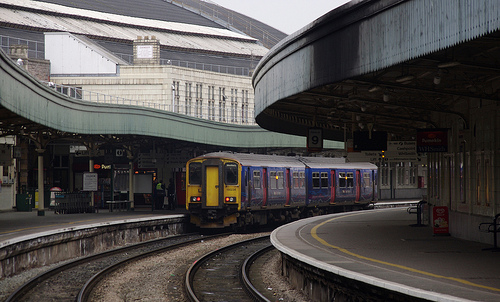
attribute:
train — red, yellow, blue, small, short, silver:
[181, 149, 381, 231]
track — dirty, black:
[6, 226, 236, 301]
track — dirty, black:
[185, 232, 281, 301]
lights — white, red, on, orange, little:
[222, 194, 238, 205]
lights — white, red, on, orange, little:
[187, 193, 204, 204]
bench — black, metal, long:
[405, 197, 429, 227]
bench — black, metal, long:
[52, 190, 101, 214]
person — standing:
[164, 178, 179, 211]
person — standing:
[155, 177, 166, 214]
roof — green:
[0, 49, 345, 149]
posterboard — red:
[432, 206, 450, 236]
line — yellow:
[308, 206, 498, 299]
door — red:
[326, 167, 338, 201]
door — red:
[350, 166, 364, 207]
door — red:
[283, 167, 293, 207]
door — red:
[259, 163, 270, 211]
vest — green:
[154, 181, 163, 192]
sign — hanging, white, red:
[92, 156, 117, 178]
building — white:
[50, 65, 257, 122]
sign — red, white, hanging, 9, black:
[305, 124, 327, 152]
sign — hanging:
[350, 127, 389, 154]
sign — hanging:
[413, 124, 450, 154]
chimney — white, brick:
[130, 34, 162, 64]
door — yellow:
[203, 165, 222, 207]